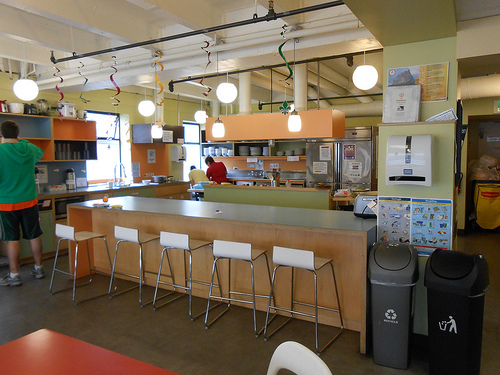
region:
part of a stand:
[308, 288, 323, 315]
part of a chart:
[413, 185, 440, 207]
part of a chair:
[219, 222, 264, 277]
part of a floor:
[193, 340, 233, 371]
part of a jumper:
[6, 173, 34, 194]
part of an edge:
[388, 22, 424, 54]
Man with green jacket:
[0, 118, 46, 284]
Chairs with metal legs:
[48, 221, 345, 354]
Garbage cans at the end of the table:
[373, 237, 485, 372]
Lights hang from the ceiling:
[11, 62, 378, 138]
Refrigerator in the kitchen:
[304, 125, 373, 189]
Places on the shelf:
[237, 142, 270, 157]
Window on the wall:
[85, 110, 123, 182]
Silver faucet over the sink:
[113, 162, 128, 188]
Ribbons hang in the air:
[51, 38, 307, 102]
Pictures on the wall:
[376, 193, 453, 256]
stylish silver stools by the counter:
[58, 225, 328, 335]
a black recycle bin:
[366, 237, 422, 366]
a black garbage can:
[428, 250, 489, 369]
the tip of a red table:
[19, 317, 153, 373]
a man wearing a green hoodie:
[1, 118, 51, 285]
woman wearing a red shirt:
[206, 152, 232, 181]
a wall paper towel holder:
[381, 132, 445, 198]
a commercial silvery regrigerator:
[308, 137, 375, 189]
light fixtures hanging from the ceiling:
[18, 20, 395, 105]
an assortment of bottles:
[57, 140, 95, 163]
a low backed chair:
[41, 215, 116, 306]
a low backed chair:
[99, 221, 174, 308]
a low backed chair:
[153, 223, 223, 319]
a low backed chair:
[191, 230, 276, 337]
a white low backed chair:
[256, 241, 347, 355]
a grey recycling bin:
[366, 236, 418, 372]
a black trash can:
[422, 239, 492, 373]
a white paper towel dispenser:
[381, 129, 434, 191]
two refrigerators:
[301, 128, 374, 192]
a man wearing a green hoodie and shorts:
[0, 119, 52, 292]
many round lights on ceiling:
[20, 60, 418, 145]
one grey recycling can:
[358, 198, 430, 370]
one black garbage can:
[414, 248, 496, 362]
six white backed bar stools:
[41, 198, 383, 328]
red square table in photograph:
[8, 308, 172, 373]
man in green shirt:
[2, 120, 49, 265]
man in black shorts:
[4, 194, 68, 265]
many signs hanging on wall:
[377, 48, 452, 260]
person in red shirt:
[200, 122, 232, 189]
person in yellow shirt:
[181, 162, 209, 193]